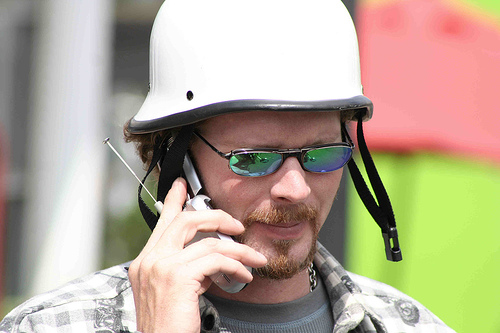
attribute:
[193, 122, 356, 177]
glasses — black, here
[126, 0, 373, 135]
helmet — white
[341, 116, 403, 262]
strap — black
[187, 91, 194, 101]
dot — black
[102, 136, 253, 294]
phone — silver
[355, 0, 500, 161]
wall — here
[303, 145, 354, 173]
lens — reflective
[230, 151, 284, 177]
lens — reflective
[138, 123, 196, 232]
strap — black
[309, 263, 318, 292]
chain — silver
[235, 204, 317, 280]
facial hair — brown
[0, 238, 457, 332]
shirt — gray, grey